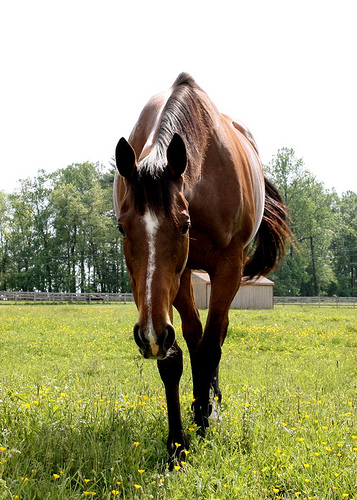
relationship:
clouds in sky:
[0, 0, 354, 71] [236, 29, 322, 139]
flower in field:
[137, 460, 160, 469] [3, 296, 356, 496]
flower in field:
[137, 467, 145, 475] [3, 296, 356, 496]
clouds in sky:
[0, 0, 354, 71] [2, 0, 355, 293]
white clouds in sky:
[269, 44, 338, 97] [0, 0, 356, 216]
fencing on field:
[0, 290, 134, 302] [3, 296, 356, 496]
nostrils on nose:
[137, 320, 174, 353] [123, 300, 178, 364]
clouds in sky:
[0, 0, 354, 71] [2, 5, 355, 209]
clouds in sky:
[0, 0, 354, 71] [2, 22, 355, 192]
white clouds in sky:
[269, 44, 338, 97] [25, 39, 355, 188]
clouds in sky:
[0, 0, 354, 71] [8, 14, 342, 187]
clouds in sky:
[32, 37, 134, 93] [2, 5, 355, 209]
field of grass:
[3, 296, 356, 496] [231, 313, 355, 497]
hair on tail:
[258, 173, 302, 275] [241, 175, 301, 284]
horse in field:
[110, 70, 304, 475] [3, 296, 356, 496]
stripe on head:
[138, 210, 178, 352] [103, 126, 202, 370]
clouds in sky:
[0, 0, 354, 71] [6, 37, 118, 149]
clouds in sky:
[0, 0, 354, 71] [12, 42, 353, 101]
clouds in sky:
[0, 0, 354, 71] [49, 3, 326, 108]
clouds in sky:
[0, 0, 354, 71] [8, 51, 355, 191]